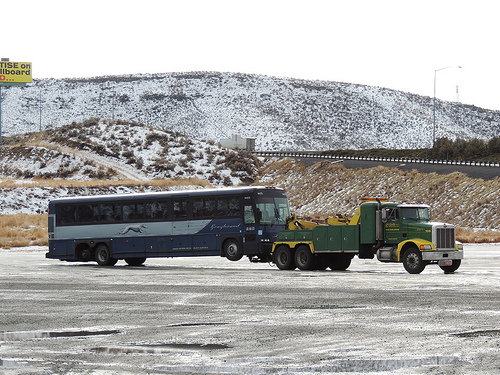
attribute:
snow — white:
[3, 76, 497, 147]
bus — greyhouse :
[38, 179, 284, 269]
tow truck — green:
[276, 192, 472, 281]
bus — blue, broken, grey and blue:
[46, 187, 290, 266]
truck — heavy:
[267, 190, 467, 274]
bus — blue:
[37, 173, 294, 263]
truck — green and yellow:
[271, 189, 472, 281]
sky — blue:
[4, 6, 497, 128]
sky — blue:
[9, 9, 497, 94]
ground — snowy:
[395, 168, 434, 215]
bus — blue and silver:
[47, 187, 283, 274]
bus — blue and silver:
[24, 144, 299, 304]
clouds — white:
[304, 19, 394, 67]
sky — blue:
[72, 3, 225, 66]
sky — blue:
[136, 3, 447, 64]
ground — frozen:
[96, 303, 407, 359]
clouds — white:
[21, 7, 119, 64]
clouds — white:
[251, 2, 360, 73]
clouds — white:
[390, 7, 489, 85]